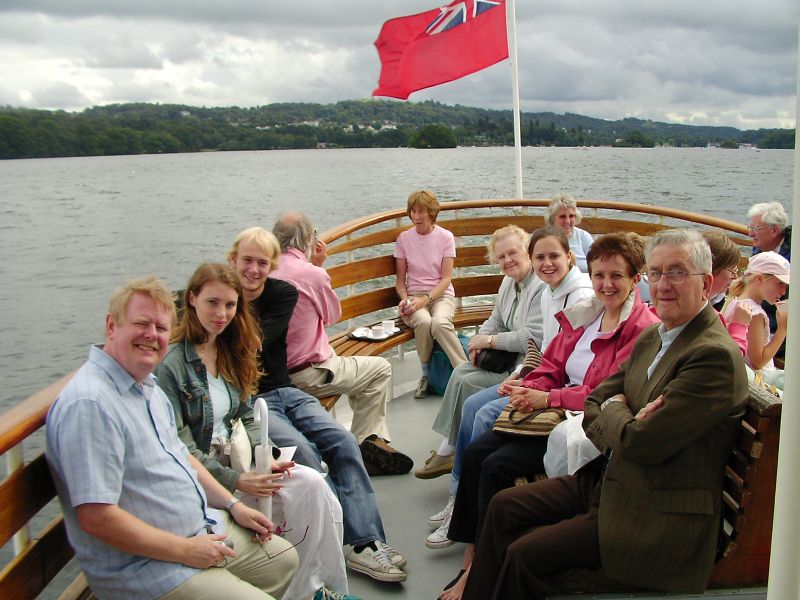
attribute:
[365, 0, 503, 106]
flag — red, British Ensign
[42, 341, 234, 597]
shirt — button down, light blue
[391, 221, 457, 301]
shirt — pink, short sleeved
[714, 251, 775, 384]
girl — young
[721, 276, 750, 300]
pony tail — blonde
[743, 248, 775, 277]
cap — light pink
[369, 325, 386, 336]
coffee mug — white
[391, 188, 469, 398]
woman — sitting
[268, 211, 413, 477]
man — sitting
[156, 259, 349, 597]
woman — sitting